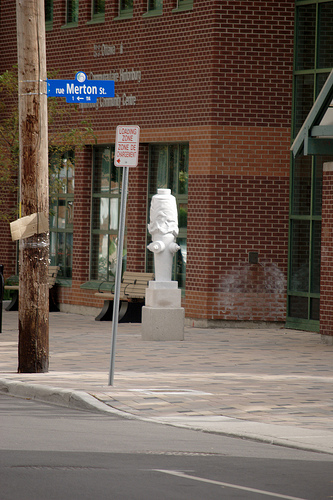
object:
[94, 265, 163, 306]
wireless mice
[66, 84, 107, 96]
merton st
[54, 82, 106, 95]
name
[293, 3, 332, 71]
green window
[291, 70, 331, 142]
green window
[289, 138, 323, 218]
green window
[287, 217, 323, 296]
green window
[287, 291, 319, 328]
green window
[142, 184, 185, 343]
grey marble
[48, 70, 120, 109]
blue sky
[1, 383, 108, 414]
curb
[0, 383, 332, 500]
road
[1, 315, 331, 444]
sidewalk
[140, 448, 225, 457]
manhole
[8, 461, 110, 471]
manhole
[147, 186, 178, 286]
hydrant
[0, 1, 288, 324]
brick wall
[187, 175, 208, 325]
brick wall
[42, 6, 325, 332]
brick building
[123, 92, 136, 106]
word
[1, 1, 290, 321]
building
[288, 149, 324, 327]
door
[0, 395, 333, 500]
street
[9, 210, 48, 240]
cardboard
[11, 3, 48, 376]
pole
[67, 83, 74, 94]
m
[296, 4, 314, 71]
window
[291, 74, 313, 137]
window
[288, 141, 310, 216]
window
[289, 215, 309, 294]
window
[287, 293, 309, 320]
window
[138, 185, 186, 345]
statue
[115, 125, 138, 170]
sign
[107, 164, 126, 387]
post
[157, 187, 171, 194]
top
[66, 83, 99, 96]
letters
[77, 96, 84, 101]
arrow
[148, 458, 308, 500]
line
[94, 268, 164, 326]
benches